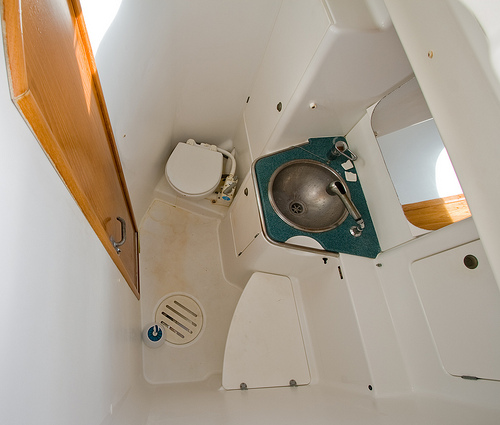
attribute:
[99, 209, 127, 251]
handle — silver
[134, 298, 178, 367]
plug floor — blue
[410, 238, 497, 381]
washer — round, black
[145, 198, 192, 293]
stain — yellow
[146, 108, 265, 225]
toilet — white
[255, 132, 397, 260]
sink — stainless steel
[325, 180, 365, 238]
faucet — stainless steel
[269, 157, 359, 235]
bowl — silver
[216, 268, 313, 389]
seat — foldable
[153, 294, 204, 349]
drain — round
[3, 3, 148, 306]
wooden door — long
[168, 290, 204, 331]
white grate — round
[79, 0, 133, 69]
light — shining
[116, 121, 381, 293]
bathroom — white, small, empty, clean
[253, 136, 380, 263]
sink — dark blue, chrome, empty, small, deep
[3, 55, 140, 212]
door — brown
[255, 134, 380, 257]
counter top —  blue